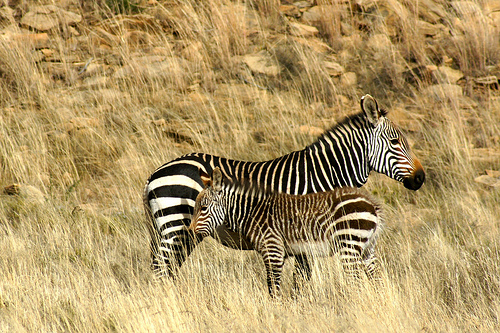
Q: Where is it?
A: This is at the field.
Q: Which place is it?
A: It is a field.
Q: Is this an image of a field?
A: Yes, it is showing a field.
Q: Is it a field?
A: Yes, it is a field.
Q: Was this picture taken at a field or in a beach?
A: It was taken at a field.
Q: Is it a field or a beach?
A: It is a field.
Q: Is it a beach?
A: No, it is a field.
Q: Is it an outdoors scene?
A: Yes, it is outdoors.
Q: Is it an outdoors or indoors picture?
A: It is outdoors.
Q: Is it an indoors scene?
A: No, it is outdoors.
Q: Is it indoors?
A: No, it is outdoors.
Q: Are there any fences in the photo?
A: No, there are no fences.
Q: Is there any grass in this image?
A: Yes, there is grass.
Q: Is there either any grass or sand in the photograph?
A: Yes, there is grass.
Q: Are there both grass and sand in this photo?
A: No, there is grass but no sand.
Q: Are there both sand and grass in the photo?
A: No, there is grass but no sand.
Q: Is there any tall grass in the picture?
A: Yes, there is tall grass.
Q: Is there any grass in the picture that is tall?
A: Yes, there is grass that is tall.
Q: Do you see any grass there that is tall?
A: Yes, there is grass that is tall.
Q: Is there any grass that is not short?
A: Yes, there is tall grass.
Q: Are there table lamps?
A: No, there are no table lamps.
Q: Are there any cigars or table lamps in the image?
A: No, there are no table lamps or cigars.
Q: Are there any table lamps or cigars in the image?
A: No, there are no table lamps or cigars.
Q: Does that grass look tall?
A: Yes, the grass is tall.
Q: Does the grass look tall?
A: Yes, the grass is tall.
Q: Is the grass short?
A: No, the grass is tall.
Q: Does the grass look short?
A: No, the grass is tall.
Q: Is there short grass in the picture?
A: No, there is grass but it is tall.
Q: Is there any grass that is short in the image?
A: No, there is grass but it is tall.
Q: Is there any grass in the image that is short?
A: No, there is grass but it is tall.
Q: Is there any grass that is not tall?
A: No, there is grass but it is tall.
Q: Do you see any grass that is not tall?
A: No, there is grass but it is tall.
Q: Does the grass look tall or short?
A: The grass is tall.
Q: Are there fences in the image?
A: No, there are no fences.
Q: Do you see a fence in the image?
A: No, there are no fences.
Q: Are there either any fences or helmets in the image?
A: No, there are no fences or helmets.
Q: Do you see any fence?
A: No, there are no fences.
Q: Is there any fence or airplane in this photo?
A: No, there are no fences or airplanes.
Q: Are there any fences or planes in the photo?
A: No, there are no fences or planes.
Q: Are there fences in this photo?
A: No, there are no fences.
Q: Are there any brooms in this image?
A: No, there are no brooms.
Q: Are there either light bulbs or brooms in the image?
A: No, there are no brooms or light bulbs.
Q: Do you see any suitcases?
A: No, there are no suitcases.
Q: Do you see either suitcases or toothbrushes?
A: No, there are no suitcases or toothbrushes.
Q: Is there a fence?
A: No, there are no fences.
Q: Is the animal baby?
A: Yes, the animal is a baby.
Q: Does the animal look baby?
A: Yes, the animal is a baby.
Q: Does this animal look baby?
A: Yes, the animal is a baby.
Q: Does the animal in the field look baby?
A: Yes, the animal is a baby.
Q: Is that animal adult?
A: No, the animal is a baby.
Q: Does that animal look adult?
A: No, the animal is a baby.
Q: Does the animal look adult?
A: No, the animal is a baby.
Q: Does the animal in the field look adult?
A: No, the animal is a baby.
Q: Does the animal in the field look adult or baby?
A: The animal is a baby.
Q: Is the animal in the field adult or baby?
A: The animal is a baby.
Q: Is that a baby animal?
A: Yes, that is a baby animal.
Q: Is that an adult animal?
A: No, that is a baby animal.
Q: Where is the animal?
A: The animal is in the field.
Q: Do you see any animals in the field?
A: Yes, there is an animal in the field.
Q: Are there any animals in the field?
A: Yes, there is an animal in the field.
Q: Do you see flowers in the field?
A: No, there is an animal in the field.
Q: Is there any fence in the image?
A: No, there are no fences.